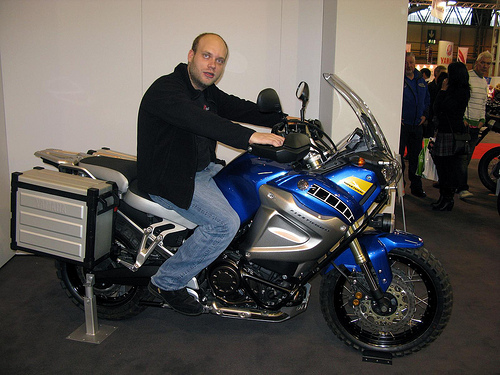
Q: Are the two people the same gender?
A: No, they are both male and female.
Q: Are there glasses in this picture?
A: No, there are no glasses.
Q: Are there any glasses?
A: No, there are no glasses.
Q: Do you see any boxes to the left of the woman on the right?
A: Yes, there is a box to the left of the woman.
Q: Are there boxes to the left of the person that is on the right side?
A: Yes, there is a box to the left of the woman.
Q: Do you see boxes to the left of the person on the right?
A: Yes, there is a box to the left of the woman.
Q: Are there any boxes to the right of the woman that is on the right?
A: No, the box is to the left of the woman.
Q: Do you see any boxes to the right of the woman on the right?
A: No, the box is to the left of the woman.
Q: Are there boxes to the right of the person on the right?
A: No, the box is to the left of the woman.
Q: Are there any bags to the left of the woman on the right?
A: No, there is a box to the left of the woman.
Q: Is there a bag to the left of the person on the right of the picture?
A: No, there is a box to the left of the woman.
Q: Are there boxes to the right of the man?
A: Yes, there is a box to the right of the man.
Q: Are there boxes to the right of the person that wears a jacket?
A: Yes, there is a box to the right of the man.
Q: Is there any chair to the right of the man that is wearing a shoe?
A: No, there is a box to the right of the man.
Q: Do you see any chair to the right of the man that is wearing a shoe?
A: No, there is a box to the right of the man.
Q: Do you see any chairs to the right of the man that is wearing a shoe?
A: No, there is a box to the right of the man.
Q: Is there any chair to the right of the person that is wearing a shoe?
A: No, there is a box to the right of the man.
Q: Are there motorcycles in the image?
A: Yes, there is a motorcycle.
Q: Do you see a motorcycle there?
A: Yes, there is a motorcycle.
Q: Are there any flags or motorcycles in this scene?
A: Yes, there is a motorcycle.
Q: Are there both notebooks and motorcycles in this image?
A: No, there is a motorcycle but no notebooks.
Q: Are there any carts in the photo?
A: No, there are no carts.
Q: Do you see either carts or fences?
A: No, there are no carts or fences.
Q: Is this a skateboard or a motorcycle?
A: This is a motorcycle.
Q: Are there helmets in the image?
A: No, there are no helmets.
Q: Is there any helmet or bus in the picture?
A: No, there are no helmets or buses.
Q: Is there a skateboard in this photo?
A: No, there are no skateboards.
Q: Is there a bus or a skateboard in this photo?
A: No, there are no skateboards or buses.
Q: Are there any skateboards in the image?
A: No, there are no skateboards.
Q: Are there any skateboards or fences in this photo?
A: No, there are no skateboards or fences.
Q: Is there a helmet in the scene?
A: No, there are no helmets.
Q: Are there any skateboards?
A: No, there are no skateboards.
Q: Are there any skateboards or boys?
A: No, there are no skateboards or boys.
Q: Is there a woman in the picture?
A: Yes, there is a woman.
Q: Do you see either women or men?
A: Yes, there is a woman.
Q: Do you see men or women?
A: Yes, there is a woman.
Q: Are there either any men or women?
A: Yes, there is a woman.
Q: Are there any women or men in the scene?
A: Yes, there is a woman.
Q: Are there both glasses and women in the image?
A: No, there is a woman but no glasses.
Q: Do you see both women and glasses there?
A: No, there is a woman but no glasses.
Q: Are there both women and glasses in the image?
A: No, there is a woman but no glasses.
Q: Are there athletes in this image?
A: No, there are no athletes.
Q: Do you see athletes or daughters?
A: No, there are no athletes or daughters.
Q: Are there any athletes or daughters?
A: No, there are no athletes or daughters.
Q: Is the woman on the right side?
A: Yes, the woman is on the right of the image.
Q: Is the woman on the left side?
A: No, the woman is on the right of the image.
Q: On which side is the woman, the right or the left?
A: The woman is on the right of the image.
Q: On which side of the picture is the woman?
A: The woman is on the right of the image.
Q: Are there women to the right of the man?
A: Yes, there is a woman to the right of the man.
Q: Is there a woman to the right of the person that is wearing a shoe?
A: Yes, there is a woman to the right of the man.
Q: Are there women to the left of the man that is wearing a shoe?
A: No, the woman is to the right of the man.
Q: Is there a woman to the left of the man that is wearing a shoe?
A: No, the woman is to the right of the man.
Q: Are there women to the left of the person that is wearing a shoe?
A: No, the woman is to the right of the man.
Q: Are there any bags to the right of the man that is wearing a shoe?
A: No, there is a woman to the right of the man.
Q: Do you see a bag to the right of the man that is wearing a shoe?
A: No, there is a woman to the right of the man.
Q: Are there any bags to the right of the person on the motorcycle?
A: No, there is a woman to the right of the man.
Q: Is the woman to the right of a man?
A: Yes, the woman is to the right of a man.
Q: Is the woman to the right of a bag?
A: No, the woman is to the right of a man.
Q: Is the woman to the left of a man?
A: No, the woman is to the right of a man.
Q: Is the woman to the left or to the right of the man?
A: The woman is to the right of the man.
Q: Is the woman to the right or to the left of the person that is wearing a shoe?
A: The woman is to the right of the man.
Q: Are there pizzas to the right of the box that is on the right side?
A: No, there is a woman to the right of the box.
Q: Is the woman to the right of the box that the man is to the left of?
A: Yes, the woman is to the right of the box.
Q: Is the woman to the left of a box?
A: No, the woman is to the right of a box.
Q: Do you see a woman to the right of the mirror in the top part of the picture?
A: Yes, there is a woman to the right of the mirror.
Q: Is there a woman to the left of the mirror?
A: No, the woman is to the right of the mirror.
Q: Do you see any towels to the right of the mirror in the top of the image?
A: No, there is a woman to the right of the mirror.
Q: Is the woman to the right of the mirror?
A: Yes, the woman is to the right of the mirror.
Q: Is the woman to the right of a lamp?
A: No, the woman is to the right of the mirror.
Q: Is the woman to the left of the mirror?
A: No, the woman is to the right of the mirror.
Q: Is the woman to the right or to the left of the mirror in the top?
A: The woman is to the right of the mirror.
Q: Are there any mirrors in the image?
A: Yes, there is a mirror.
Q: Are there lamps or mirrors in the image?
A: Yes, there is a mirror.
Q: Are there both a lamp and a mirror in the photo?
A: No, there is a mirror but no lamps.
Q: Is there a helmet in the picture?
A: No, there are no helmets.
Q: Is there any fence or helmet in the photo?
A: No, there are no helmets or fences.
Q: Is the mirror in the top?
A: Yes, the mirror is in the top of the image.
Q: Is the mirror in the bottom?
A: No, the mirror is in the top of the image.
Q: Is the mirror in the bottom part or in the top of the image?
A: The mirror is in the top of the image.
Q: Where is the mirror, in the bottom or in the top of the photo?
A: The mirror is in the top of the image.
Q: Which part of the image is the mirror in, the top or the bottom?
A: The mirror is in the top of the image.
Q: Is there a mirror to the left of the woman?
A: Yes, there is a mirror to the left of the woman.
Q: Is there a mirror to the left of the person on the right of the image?
A: Yes, there is a mirror to the left of the woman.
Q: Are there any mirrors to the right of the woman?
A: No, the mirror is to the left of the woman.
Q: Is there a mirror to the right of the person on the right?
A: No, the mirror is to the left of the woman.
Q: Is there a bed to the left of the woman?
A: No, there is a mirror to the left of the woman.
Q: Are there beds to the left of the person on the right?
A: No, there is a mirror to the left of the woman.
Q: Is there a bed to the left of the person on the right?
A: No, there is a mirror to the left of the woman.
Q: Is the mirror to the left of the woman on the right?
A: Yes, the mirror is to the left of the woman.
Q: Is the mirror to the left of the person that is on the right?
A: Yes, the mirror is to the left of the woman.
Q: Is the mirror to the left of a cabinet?
A: No, the mirror is to the left of the woman.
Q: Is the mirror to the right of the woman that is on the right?
A: No, the mirror is to the left of the woman.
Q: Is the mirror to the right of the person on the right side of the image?
A: No, the mirror is to the left of the woman.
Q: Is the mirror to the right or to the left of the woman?
A: The mirror is to the left of the woman.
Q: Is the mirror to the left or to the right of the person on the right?
A: The mirror is to the left of the woman.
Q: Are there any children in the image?
A: No, there are no children.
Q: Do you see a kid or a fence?
A: No, there are no children or fences.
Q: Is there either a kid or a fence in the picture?
A: No, there are no children or fences.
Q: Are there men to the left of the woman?
A: Yes, there is a man to the left of the woman.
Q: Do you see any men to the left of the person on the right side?
A: Yes, there is a man to the left of the woman.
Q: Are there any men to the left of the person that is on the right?
A: Yes, there is a man to the left of the woman.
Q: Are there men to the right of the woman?
A: No, the man is to the left of the woman.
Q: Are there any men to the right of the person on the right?
A: No, the man is to the left of the woman.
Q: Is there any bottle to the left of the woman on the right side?
A: No, there is a man to the left of the woman.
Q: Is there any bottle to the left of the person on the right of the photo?
A: No, there is a man to the left of the woman.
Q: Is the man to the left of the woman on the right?
A: Yes, the man is to the left of the woman.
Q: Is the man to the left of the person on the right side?
A: Yes, the man is to the left of the woman.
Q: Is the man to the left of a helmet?
A: No, the man is to the left of the woman.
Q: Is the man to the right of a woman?
A: No, the man is to the left of a woman.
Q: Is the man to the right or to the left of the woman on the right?
A: The man is to the left of the woman.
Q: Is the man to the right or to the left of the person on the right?
A: The man is to the left of the woman.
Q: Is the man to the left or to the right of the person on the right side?
A: The man is to the left of the woman.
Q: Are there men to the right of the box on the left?
A: Yes, there is a man to the right of the box.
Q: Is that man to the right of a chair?
A: No, the man is to the right of the box.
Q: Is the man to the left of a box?
A: No, the man is to the right of a box.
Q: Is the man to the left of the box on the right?
A: Yes, the man is to the left of the box.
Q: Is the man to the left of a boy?
A: No, the man is to the left of the box.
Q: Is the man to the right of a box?
A: No, the man is to the left of a box.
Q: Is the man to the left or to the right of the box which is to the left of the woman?
A: The man is to the left of the box.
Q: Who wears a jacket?
A: The man wears a jacket.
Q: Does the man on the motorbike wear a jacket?
A: Yes, the man wears a jacket.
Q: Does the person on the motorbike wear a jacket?
A: Yes, the man wears a jacket.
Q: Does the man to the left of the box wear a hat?
A: No, the man wears a jacket.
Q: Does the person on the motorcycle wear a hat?
A: No, the man wears a jacket.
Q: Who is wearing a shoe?
A: The man is wearing a shoe.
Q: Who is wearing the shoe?
A: The man is wearing a shoe.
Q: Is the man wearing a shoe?
A: Yes, the man is wearing a shoe.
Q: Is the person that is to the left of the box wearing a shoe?
A: Yes, the man is wearing a shoe.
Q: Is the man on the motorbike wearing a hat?
A: No, the man is wearing a shoe.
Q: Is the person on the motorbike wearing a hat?
A: No, the man is wearing a shoe.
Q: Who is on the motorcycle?
A: The man is on the motorcycle.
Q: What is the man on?
A: The man is on the motorcycle.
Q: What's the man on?
A: The man is on the motorcycle.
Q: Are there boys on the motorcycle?
A: No, there is a man on the motorcycle.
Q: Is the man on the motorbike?
A: Yes, the man is on the motorbike.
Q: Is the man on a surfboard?
A: No, the man is on the motorbike.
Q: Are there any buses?
A: No, there are no buses.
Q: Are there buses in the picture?
A: No, there are no buses.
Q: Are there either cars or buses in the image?
A: No, there are no buses or cars.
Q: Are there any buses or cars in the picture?
A: No, there are no buses or cars.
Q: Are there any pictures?
A: No, there are no pictures.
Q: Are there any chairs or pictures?
A: No, there are no pictures or chairs.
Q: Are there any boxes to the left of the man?
A: Yes, there is a box to the left of the man.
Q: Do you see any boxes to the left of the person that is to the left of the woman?
A: Yes, there is a box to the left of the man.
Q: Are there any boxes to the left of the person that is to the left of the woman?
A: Yes, there is a box to the left of the man.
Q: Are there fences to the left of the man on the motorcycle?
A: No, there is a box to the left of the man.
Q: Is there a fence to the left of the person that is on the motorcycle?
A: No, there is a box to the left of the man.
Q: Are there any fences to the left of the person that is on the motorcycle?
A: No, there is a box to the left of the man.